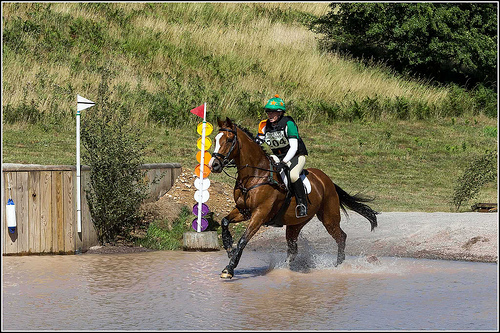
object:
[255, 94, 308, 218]
rider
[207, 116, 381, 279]
horse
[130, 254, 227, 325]
water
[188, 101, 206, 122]
flag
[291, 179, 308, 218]
boots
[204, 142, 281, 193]
harness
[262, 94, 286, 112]
helmet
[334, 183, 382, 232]
tail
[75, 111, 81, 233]
pole